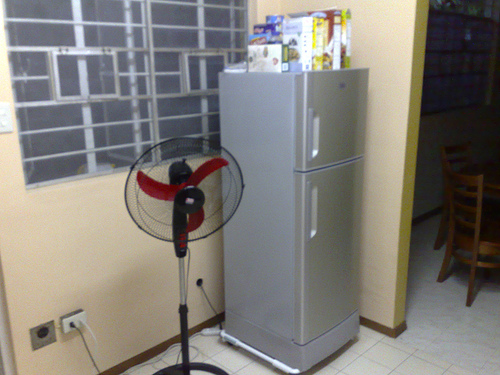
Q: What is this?
A: Fan.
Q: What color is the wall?
A: Yellow.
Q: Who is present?
A: Nobody.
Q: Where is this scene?
A: In a kitchen.